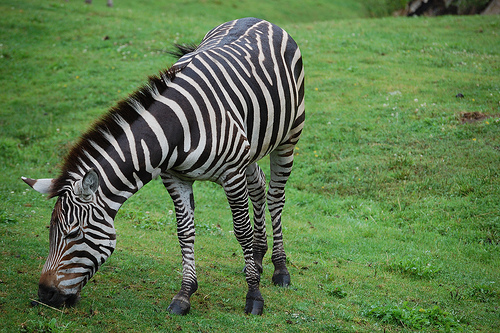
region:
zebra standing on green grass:
[23, 15, 309, 317]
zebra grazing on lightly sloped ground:
[15, 107, 121, 317]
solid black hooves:
[160, 261, 290, 316]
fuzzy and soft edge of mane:
[55, 85, 166, 175]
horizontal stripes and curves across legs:
[161, 166, 301, 256]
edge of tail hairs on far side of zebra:
[156, 30, 196, 65]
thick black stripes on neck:
[117, 85, 187, 175]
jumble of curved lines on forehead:
[50, 195, 92, 232]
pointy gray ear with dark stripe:
[17, 166, 52, 201]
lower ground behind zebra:
[211, 1, 497, 61]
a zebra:
[4, 15, 347, 330]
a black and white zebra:
[21, 22, 334, 324]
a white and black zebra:
[4, 20, 312, 310]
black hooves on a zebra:
[150, 235, 365, 330]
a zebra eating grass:
[15, 20, 360, 327]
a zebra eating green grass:
[23, 28, 322, 330]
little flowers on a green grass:
[323, 54, 488, 162]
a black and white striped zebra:
[3, 12, 378, 322]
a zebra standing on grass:
[17, 6, 494, 326]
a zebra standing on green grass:
[26, 33, 485, 310]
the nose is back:
[33, 285, 78, 310]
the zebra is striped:
[20, 15, 311, 315]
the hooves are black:
[167, 260, 293, 317]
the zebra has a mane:
[45, 68, 187, 199]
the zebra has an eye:
[63, 222, 84, 244]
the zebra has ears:
[17, 163, 105, 205]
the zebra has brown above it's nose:
[35, 265, 87, 289]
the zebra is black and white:
[15, 13, 307, 318]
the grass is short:
[3, 2, 494, 327]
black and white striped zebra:
[21, 22, 306, 315]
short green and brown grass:
[300, 192, 373, 245]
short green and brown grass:
[311, 238, 390, 298]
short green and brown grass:
[381, 221, 436, 297]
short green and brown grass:
[308, 32, 363, 92]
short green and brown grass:
[359, 41, 433, 117]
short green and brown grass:
[302, 114, 395, 188]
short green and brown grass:
[5, 6, 85, 59]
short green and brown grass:
[24, 62, 122, 128]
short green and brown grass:
[119, 240, 155, 293]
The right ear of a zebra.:
[71, 165, 101, 205]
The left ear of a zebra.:
[18, 168, 60, 199]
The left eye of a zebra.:
[55, 222, 89, 243]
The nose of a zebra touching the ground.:
[35, 274, 62, 303]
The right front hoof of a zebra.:
[165, 293, 189, 316]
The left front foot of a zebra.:
[239, 297, 270, 317]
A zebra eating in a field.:
[22, 10, 314, 315]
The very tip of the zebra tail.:
[166, 40, 191, 57]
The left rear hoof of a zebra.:
[269, 268, 295, 289]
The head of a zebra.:
[17, 172, 117, 309]